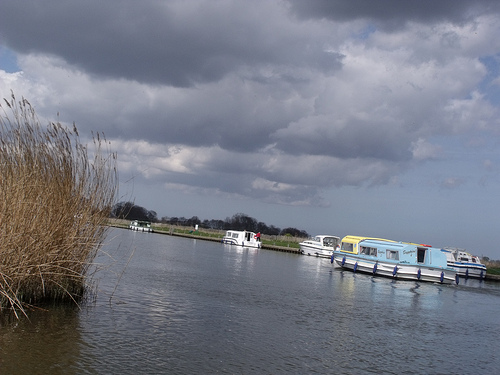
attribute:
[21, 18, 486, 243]
sky — stormy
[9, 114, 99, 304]
plant — brown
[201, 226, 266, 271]
boat — white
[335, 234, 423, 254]
roof — yellow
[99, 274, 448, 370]
water — calm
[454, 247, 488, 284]
boat — white, blue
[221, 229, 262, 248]
boat — small, white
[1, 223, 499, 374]
water — brown, calm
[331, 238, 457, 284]
boat — blue, white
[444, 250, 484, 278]
boat — white, blue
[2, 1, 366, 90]
cloud — dark, gray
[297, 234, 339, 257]
boat — white, motorboat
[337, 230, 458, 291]
boat — light blue, yellow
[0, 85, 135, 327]
bushes — tall, tan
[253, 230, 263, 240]
jacket — red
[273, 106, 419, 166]
cloud — gray